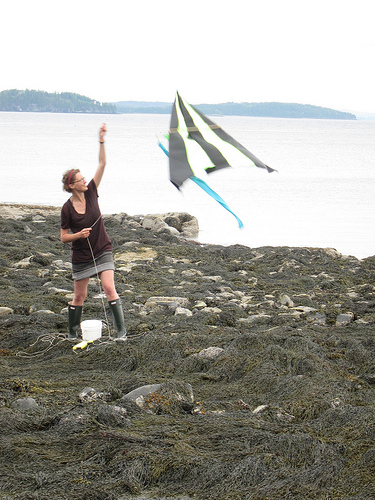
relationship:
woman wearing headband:
[54, 119, 129, 343] [65, 165, 76, 187]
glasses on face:
[70, 175, 87, 182] [72, 167, 93, 193]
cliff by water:
[2, 199, 370, 499] [0, 110, 373, 261]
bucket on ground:
[80, 316, 101, 341] [0, 204, 372, 495]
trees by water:
[0, 89, 117, 109] [0, 110, 373, 261]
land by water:
[114, 100, 355, 120] [0, 110, 373, 261]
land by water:
[0, 203, 371, 498] [0, 110, 373, 261]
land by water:
[0, 88, 357, 118] [0, 110, 373, 261]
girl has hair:
[56, 120, 134, 345] [60, 164, 83, 196]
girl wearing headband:
[56, 120, 134, 345] [65, 165, 76, 187]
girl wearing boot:
[59, 121, 126, 342] [63, 300, 86, 343]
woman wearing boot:
[54, 119, 129, 343] [106, 293, 128, 340]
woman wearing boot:
[54, 119, 129, 343] [66, 303, 88, 345]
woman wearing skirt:
[39, 149, 159, 344] [68, 251, 117, 280]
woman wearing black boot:
[55, 105, 134, 364] [95, 286, 136, 347]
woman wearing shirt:
[54, 119, 129, 343] [59, 177, 111, 264]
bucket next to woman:
[80, 316, 101, 341] [54, 119, 129, 343]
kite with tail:
[152, 87, 288, 235] [154, 130, 247, 231]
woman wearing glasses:
[41, 144, 149, 351] [70, 175, 87, 182]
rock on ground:
[121, 382, 193, 413] [0, 204, 372, 495]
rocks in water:
[126, 212, 197, 239] [0, 110, 373, 261]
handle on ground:
[73, 335, 87, 356] [12, 335, 348, 495]